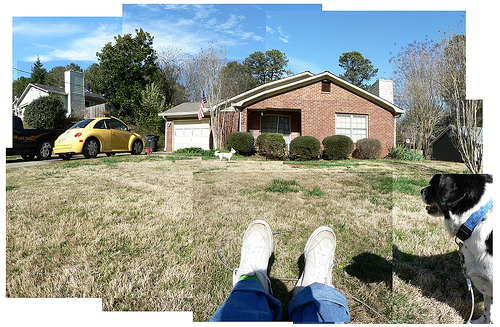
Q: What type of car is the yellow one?
A: VW Beetle.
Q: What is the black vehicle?
A: Truck.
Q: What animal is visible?
A: Dog.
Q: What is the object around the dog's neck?
A: A collar.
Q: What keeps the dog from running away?
A: A leash.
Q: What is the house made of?
A: Brick.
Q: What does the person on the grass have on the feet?
A: Athletic shoes.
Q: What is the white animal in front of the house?
A: Dog.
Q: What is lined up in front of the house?
A: Bushes.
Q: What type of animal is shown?
A: Dog.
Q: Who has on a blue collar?
A: The dog.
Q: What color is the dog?
A: Black and white.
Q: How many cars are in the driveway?
A: Two.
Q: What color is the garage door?
A: White.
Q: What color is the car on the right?
A: Yellow.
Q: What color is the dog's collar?
A: Blue.